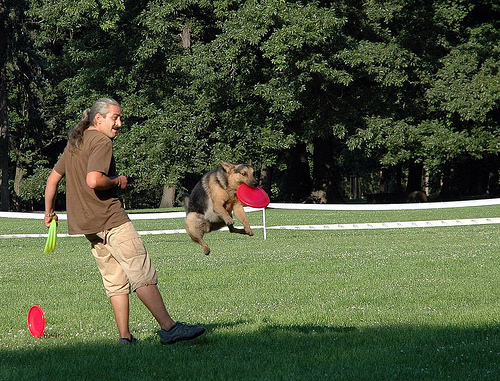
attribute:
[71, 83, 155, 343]
man — standing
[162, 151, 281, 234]
dog — in air, jumping, brown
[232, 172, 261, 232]
frisbee — red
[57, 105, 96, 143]
ponytail — long, grey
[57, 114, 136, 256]
shirt — brown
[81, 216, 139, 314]
shorts — tan, khaki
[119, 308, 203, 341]
shoes — grey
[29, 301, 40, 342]
frisbee — red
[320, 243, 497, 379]
field — grassy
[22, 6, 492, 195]
trees — tall, green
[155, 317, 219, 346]
foot — lifted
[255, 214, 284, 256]
pole — white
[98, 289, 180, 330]
legs — bare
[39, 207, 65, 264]
frisbees — yellow